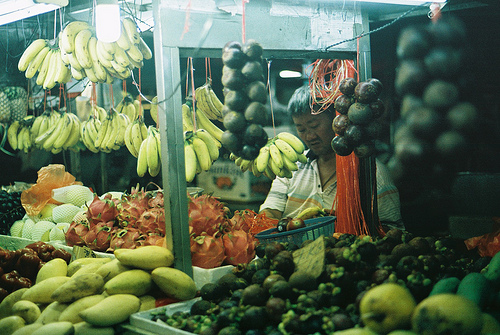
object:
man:
[291, 95, 330, 156]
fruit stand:
[0, 0, 499, 332]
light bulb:
[92, 1, 121, 45]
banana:
[77, 50, 88, 58]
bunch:
[63, 43, 154, 79]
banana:
[50, 59, 65, 85]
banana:
[66, 27, 70, 48]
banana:
[26, 43, 39, 61]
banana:
[34, 53, 41, 71]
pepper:
[5, 250, 20, 268]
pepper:
[28, 242, 35, 246]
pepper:
[40, 247, 54, 255]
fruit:
[273, 214, 307, 229]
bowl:
[253, 215, 335, 240]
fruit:
[225, 54, 238, 69]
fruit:
[228, 100, 241, 108]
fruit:
[252, 108, 263, 120]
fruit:
[246, 61, 257, 78]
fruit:
[240, 147, 255, 155]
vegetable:
[99, 304, 131, 321]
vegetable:
[34, 282, 56, 294]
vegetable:
[129, 252, 161, 264]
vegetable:
[20, 303, 34, 313]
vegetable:
[114, 275, 149, 288]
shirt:
[267, 157, 359, 218]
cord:
[237, 1, 258, 40]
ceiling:
[163, 0, 407, 9]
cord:
[184, 4, 192, 40]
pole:
[158, 21, 197, 273]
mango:
[357, 281, 412, 329]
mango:
[411, 291, 483, 333]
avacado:
[329, 78, 386, 155]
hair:
[285, 85, 323, 111]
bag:
[475, 236, 499, 251]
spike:
[208, 239, 218, 247]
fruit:
[92, 196, 112, 216]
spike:
[85, 201, 94, 216]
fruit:
[197, 201, 212, 219]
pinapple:
[14, 101, 27, 117]